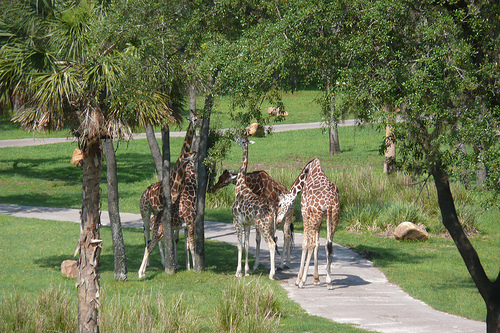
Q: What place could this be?
A: It is a park.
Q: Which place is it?
A: It is a park.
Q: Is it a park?
A: Yes, it is a park.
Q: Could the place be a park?
A: Yes, it is a park.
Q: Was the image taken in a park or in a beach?
A: It was taken at a park.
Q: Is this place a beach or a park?
A: It is a park.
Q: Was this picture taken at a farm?
A: No, the picture was taken in a park.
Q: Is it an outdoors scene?
A: Yes, it is outdoors.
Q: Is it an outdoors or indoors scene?
A: It is outdoors.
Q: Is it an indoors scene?
A: No, it is outdoors.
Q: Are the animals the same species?
A: Yes, all the animals are giraffes.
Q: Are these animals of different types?
A: No, all the animals are giraffes.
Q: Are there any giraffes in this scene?
A: Yes, there is a giraffe.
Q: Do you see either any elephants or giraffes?
A: Yes, there is a giraffe.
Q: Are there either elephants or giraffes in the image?
A: Yes, there is a giraffe.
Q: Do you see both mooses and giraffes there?
A: No, there is a giraffe but no mooses.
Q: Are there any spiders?
A: No, there are no spiders.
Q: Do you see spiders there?
A: No, there are no spiders.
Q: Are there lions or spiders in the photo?
A: No, there are no spiders or lions.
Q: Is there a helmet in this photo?
A: No, there are no helmets.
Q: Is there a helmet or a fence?
A: No, there are no helmets or fences.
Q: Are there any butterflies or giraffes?
A: Yes, there is a giraffe.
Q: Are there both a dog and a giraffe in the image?
A: No, there is a giraffe but no dogs.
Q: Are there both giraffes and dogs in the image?
A: No, there is a giraffe but no dogs.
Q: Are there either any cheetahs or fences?
A: No, there are no fences or cheetahs.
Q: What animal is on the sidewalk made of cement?
A: The animal is a giraffe.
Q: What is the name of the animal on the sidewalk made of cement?
A: The animal is a giraffe.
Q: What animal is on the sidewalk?
A: The animal is a giraffe.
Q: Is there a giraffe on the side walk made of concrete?
A: Yes, there is a giraffe on the sidewalk.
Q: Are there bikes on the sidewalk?
A: No, there is a giraffe on the sidewalk.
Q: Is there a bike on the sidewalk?
A: No, there is a giraffe on the sidewalk.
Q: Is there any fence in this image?
A: No, there are no fences.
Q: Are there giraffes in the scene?
A: Yes, there are giraffes.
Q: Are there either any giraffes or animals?
A: Yes, there are giraffes.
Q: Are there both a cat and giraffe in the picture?
A: No, there are giraffes but no cats.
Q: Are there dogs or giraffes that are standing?
A: Yes, the giraffes are standing.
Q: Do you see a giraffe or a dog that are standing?
A: Yes, the giraffes are standing.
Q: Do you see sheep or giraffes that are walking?
A: Yes, the giraffes are walking.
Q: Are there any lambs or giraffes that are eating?
A: Yes, the giraffes are eating.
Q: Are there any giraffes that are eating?
A: Yes, there are giraffes that are eating.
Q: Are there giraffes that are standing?
A: Yes, there are giraffes that are standing.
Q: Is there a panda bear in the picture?
A: No, there are no panda bears.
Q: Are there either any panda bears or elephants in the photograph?
A: No, there are no panda bears or elephants.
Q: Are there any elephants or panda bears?
A: No, there are no panda bears or elephants.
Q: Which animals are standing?
A: The animals are giraffes.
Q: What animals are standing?
A: The animals are giraffes.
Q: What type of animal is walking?
A: The animal is giraffes.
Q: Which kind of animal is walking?
A: The animal is giraffes.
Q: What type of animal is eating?
A: The animal is giraffes.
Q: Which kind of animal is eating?
A: The animal is giraffes.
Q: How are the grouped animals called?
A: The animals are giraffes.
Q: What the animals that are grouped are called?
A: The animals are giraffes.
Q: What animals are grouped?
A: The animals are giraffes.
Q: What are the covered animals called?
A: The animals are giraffes.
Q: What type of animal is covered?
A: The animal is giraffes.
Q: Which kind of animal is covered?
A: The animal is giraffes.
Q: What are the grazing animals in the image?
A: The animals are giraffes.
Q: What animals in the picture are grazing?
A: The animals are giraffes.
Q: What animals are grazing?
A: The animals are giraffes.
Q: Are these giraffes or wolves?
A: These are giraffes.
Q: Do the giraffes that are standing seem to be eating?
A: Yes, the giraffes are eating.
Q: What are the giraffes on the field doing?
A: The giraffes are eating.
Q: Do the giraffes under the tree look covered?
A: Yes, the giraffes are covered.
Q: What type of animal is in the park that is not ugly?
A: The animals are giraffes.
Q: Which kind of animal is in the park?
A: The animals are giraffes.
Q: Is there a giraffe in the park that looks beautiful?
A: Yes, there are giraffes in the park.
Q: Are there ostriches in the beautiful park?
A: No, there are giraffes in the park.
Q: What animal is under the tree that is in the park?
A: The giraffes are under the tree.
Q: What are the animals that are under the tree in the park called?
A: The animals are giraffes.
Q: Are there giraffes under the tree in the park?
A: Yes, there are giraffes under the tree.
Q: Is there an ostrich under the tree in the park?
A: No, there are giraffes under the tree.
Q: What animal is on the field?
A: The giraffes are on the field.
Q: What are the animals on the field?
A: The animals are giraffes.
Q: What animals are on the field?
A: The animals are giraffes.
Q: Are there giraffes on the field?
A: Yes, there are giraffes on the field.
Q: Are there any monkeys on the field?
A: No, there are giraffes on the field.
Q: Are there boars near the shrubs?
A: No, there are giraffes near the shrubs.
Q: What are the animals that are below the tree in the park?
A: The animals are giraffes.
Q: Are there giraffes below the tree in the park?
A: Yes, there are giraffes below the tree.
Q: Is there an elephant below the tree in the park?
A: No, there are giraffes below the tree.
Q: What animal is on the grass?
A: The giraffes are on the grass.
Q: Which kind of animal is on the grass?
A: The animals are giraffes.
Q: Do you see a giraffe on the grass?
A: Yes, there are giraffes on the grass.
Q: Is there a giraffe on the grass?
A: Yes, there are giraffes on the grass.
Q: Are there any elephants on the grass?
A: No, there are giraffes on the grass.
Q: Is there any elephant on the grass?
A: No, there are giraffes on the grass.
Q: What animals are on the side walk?
A: The animals are giraffes.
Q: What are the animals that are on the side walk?
A: The animals are giraffes.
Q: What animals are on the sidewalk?
A: The animals are giraffes.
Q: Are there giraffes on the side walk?
A: Yes, there are giraffes on the side walk.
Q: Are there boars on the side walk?
A: No, there are giraffes on the side walk.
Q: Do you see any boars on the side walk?
A: No, there are giraffes on the side walk.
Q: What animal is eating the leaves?
A: The giraffes are eating the leaves.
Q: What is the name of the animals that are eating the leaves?
A: The animals are giraffes.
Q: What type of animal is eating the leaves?
A: The animals are giraffes.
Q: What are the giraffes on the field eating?
A: The giraffes are eating leaves.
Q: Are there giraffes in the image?
A: Yes, there is a giraffe.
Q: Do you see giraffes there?
A: Yes, there is a giraffe.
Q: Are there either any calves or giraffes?
A: Yes, there is a giraffe.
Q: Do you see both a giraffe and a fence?
A: No, there is a giraffe but no fences.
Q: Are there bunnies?
A: No, there are no bunnies.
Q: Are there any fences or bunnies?
A: No, there are no bunnies or fences.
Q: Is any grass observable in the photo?
A: Yes, there is grass.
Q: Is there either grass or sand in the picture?
A: Yes, there is grass.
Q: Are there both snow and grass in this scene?
A: No, there is grass but no snow.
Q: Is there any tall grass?
A: Yes, there is tall grass.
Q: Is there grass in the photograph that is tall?
A: Yes, there is grass that is tall.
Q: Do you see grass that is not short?
A: Yes, there is tall grass.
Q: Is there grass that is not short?
A: Yes, there is tall grass.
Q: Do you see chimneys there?
A: No, there are no chimneys.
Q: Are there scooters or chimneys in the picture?
A: No, there are no chimneys or scooters.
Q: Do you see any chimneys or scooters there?
A: No, there are no chimneys or scooters.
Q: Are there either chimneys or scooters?
A: No, there are no chimneys or scooters.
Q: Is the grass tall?
A: Yes, the grass is tall.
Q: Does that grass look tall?
A: Yes, the grass is tall.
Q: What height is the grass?
A: The grass is tall.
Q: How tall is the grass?
A: The grass is tall.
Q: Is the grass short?
A: No, the grass is tall.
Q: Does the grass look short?
A: No, the grass is tall.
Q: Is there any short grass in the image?
A: No, there is grass but it is tall.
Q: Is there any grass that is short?
A: No, there is grass but it is tall.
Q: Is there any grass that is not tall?
A: No, there is grass but it is tall.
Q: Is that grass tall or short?
A: The grass is tall.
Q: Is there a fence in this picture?
A: No, there are no fences.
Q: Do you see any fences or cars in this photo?
A: No, there are no fences or cars.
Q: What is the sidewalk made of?
A: The side walk is made of concrete.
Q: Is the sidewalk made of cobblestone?
A: No, the sidewalk is made of cement.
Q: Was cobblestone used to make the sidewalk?
A: No, the sidewalk is made of cement.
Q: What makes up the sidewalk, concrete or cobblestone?
A: The sidewalk is made of concrete.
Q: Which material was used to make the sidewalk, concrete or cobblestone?
A: The sidewalk is made of concrete.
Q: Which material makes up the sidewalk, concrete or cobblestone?
A: The sidewalk is made of concrete.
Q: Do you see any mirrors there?
A: No, there are no mirrors.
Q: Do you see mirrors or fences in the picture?
A: No, there are no mirrors or fences.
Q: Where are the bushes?
A: The bushes are in the field.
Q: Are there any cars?
A: No, there are no cars.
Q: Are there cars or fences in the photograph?
A: No, there are no cars or fences.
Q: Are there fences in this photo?
A: No, there are no fences.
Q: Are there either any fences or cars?
A: No, there are no fences or cars.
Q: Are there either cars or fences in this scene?
A: No, there are no fences or cars.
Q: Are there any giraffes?
A: Yes, there is a giraffe.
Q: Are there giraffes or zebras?
A: Yes, there is a giraffe.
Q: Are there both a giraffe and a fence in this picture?
A: No, there is a giraffe but no fences.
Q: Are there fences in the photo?
A: No, there are no fences.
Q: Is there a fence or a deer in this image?
A: No, there are no fences or deer.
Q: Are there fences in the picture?
A: No, there are no fences.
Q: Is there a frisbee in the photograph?
A: No, there are no frisbees.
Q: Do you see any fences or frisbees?
A: No, there are no frisbees or fences.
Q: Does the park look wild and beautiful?
A: Yes, the park is wild and beautiful.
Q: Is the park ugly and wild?
A: No, the park is wild but beautiful.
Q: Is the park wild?
A: Yes, the park is wild.